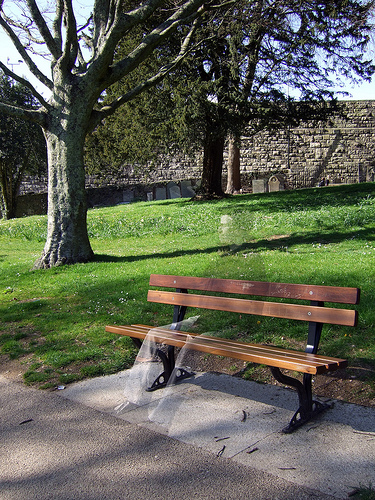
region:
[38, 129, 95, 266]
one partially sunlit tree trunk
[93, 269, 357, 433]
one wooden and metal park bench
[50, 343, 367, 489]
section of white pavement underneath bench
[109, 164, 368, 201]
section of gravestones in front of stone wall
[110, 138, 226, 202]
large shadowed tree trunk next to gravestones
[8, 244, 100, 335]
bright green grass around tree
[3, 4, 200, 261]
one large tree with bare branches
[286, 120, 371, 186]
one sunlit gray stone wall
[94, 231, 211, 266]
tree trunk shadow on green grass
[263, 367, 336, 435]
one black metal bench leg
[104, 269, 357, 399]
A wooden park bench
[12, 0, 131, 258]
A tree with no leaves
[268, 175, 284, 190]
an old worn tomb stone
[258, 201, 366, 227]
a field of green grass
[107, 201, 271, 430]
a transparent man sitting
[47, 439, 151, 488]
a gravel filled path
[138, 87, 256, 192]
a tree covered in leaves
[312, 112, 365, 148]
a wall made of stones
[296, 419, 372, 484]
a block of grey cement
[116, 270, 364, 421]
a brown bench with a black frame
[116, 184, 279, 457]
a ghost like man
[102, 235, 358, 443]
bench made of wood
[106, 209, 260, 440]
a faded image of a man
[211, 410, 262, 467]
small sticks on the ground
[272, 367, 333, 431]
metal leg on the bench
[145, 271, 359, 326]
wooden bench back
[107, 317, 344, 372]
seat of the bench is wood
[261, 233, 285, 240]
a small patch of dirt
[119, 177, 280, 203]
head stones against the wall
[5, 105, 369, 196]
a tall gray brick building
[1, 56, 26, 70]
street lights behind the tree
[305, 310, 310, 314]
a silver screw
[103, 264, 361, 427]
a wood bench in a park.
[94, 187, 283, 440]
a ghost sitting on a bench.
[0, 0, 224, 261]
a tall tree with no leaves.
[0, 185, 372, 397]
a park with lots of green grass.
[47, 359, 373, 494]
a slab of cement under a bench.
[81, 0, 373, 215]
a tree with lots of branches of green leaves.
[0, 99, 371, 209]
a brick wall in a park.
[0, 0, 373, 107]
a cloudy blue sky.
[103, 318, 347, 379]
a wooden seat on a bench.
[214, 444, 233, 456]
a piece of debris on the ground.